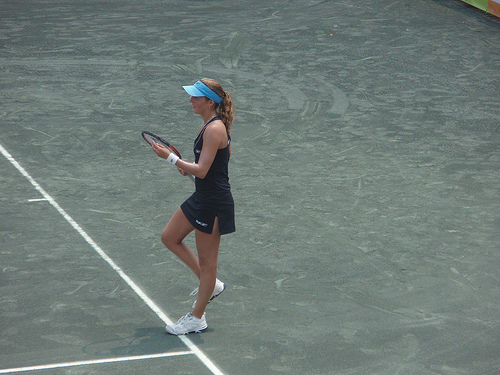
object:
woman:
[150, 78, 235, 337]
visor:
[179, 79, 223, 105]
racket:
[139, 130, 198, 181]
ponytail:
[217, 92, 234, 139]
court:
[2, 2, 498, 374]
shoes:
[165, 312, 208, 335]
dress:
[181, 117, 237, 236]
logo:
[195, 219, 208, 228]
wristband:
[166, 152, 180, 165]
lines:
[1, 146, 223, 372]